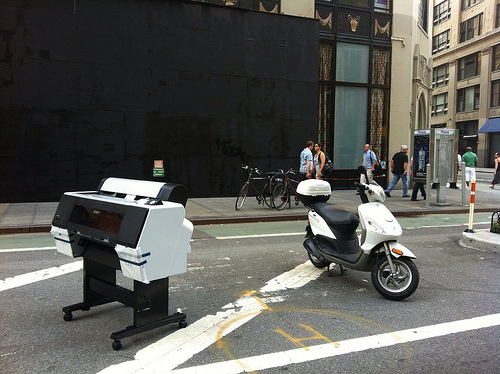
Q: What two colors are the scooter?
A: Black and white.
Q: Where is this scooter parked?
A: In the street.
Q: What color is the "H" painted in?
A: Yellow.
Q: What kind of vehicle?
A: Moped.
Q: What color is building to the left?
A: Black.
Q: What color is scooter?
A: White.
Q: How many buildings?
A: 2.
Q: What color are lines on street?
A: White.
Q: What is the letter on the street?
A: H.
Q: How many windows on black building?
A: 1.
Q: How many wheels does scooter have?
A: 2.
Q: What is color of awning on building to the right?
A: Blue.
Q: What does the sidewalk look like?
A: Paved.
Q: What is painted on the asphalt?
A: Lines.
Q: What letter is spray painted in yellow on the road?
A: H.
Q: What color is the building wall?
A: Black.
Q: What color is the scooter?
A: White.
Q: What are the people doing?
A: Walking.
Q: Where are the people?
A: Sidewalk.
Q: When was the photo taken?
A: Day time.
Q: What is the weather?
A: Sunny.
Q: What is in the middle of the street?
A: Motorcycle.